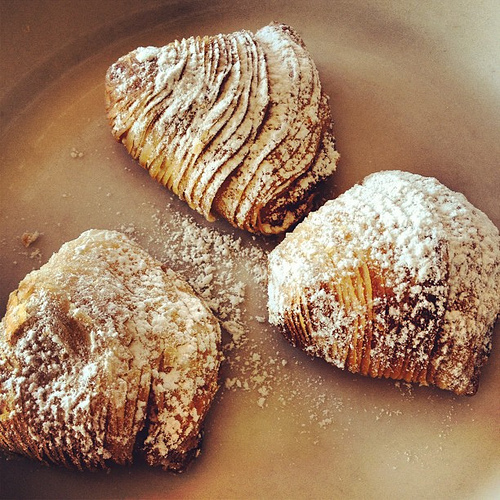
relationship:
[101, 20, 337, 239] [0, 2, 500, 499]
dessert on plate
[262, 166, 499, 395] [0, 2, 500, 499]
dessert on plate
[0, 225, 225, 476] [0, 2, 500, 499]
dessert on plate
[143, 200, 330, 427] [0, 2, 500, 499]
powdered sugar on top of plate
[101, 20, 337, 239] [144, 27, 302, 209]
dessert has sugar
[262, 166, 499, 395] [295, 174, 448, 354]
dessert has sugar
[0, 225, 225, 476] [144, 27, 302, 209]
dessert has sugar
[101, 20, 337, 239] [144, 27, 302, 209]
dessert has powdered sugar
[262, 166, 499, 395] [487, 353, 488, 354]
dessert has powdered sugar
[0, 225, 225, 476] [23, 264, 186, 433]
dessert has powdered sugar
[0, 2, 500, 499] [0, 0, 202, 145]
plate has shadow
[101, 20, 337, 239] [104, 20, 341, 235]
dessert has dessert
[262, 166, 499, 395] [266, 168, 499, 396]
dessert has dessert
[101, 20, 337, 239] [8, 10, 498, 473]
dessert appear delicate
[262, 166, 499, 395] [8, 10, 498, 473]
dessert appear delicate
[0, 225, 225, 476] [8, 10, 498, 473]
dessert appear delicate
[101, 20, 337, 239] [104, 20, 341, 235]
dessert made in dessert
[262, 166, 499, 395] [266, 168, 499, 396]
dessert made in dessert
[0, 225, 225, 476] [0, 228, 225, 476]
dessert made in dessert